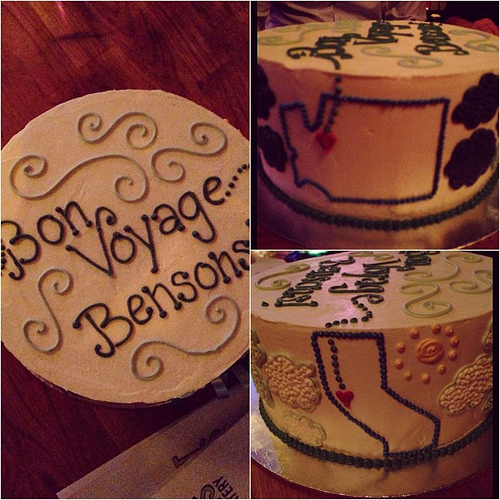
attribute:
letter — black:
[106, 230, 138, 265]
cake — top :
[256, 10, 488, 230]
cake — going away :
[1, 89, 248, 407]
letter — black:
[59, 201, 119, 281]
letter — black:
[30, 208, 67, 256]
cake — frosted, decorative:
[7, 87, 237, 374]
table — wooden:
[18, 17, 178, 64]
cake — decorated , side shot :
[248, 28, 498, 208]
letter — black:
[71, 300, 130, 360]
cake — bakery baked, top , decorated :
[256, 252, 496, 492]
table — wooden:
[6, 5, 243, 488]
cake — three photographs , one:
[207, 15, 479, 305]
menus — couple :
[115, 475, 235, 498]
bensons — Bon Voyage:
[86, 236, 250, 350]